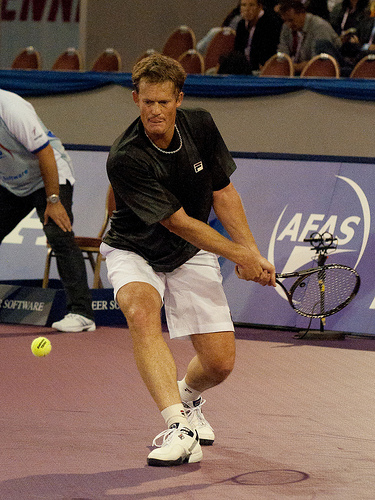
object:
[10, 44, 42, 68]
chair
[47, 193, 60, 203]
watch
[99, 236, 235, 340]
shorts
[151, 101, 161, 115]
nose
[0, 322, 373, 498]
court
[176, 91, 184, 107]
ear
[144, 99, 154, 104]
right eye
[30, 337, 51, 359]
ball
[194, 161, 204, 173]
logo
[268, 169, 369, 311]
logo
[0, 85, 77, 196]
shirt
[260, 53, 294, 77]
seat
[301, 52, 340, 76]
seat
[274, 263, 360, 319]
racket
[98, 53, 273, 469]
ear person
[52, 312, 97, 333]
shoe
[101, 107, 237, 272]
shirt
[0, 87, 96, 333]
man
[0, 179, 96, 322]
pants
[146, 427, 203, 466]
shoe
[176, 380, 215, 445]
shoe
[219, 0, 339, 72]
people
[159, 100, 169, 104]
left eye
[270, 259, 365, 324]
racquet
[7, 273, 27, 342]
air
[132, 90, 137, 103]
ear